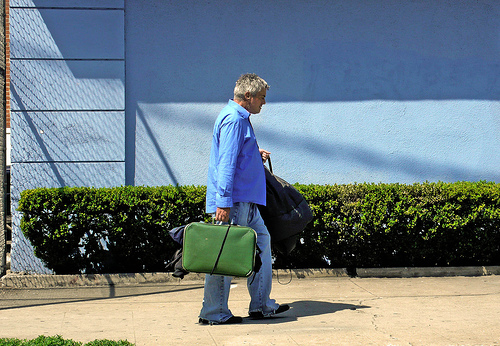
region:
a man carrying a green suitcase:
[175, 47, 314, 323]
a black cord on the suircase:
[217, 222, 229, 268]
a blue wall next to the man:
[274, 21, 474, 148]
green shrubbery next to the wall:
[334, 184, 484, 243]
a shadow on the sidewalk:
[295, 289, 371, 326]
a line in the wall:
[14, 99, 127, 119]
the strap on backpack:
[266, 154, 277, 168]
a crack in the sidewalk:
[356, 306, 396, 344]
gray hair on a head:
[240, 69, 263, 87]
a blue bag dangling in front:
[271, 186, 310, 231]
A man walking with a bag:
[167, 52, 304, 342]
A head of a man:
[216, 60, 280, 128]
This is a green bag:
[172, 212, 269, 286]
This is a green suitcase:
[173, 211, 266, 286]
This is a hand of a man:
[211, 112, 241, 226]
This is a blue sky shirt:
[201, 95, 270, 215]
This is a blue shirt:
[203, 96, 270, 216]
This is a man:
[174, 61, 301, 329]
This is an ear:
[241, 86, 255, 101]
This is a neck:
[228, 90, 254, 114]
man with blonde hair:
[224, 74, 281, 121]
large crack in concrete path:
[358, 297, 413, 344]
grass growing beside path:
[0, 326, 142, 343]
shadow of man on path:
[235, 285, 372, 335]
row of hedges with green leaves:
[321, 178, 498, 263]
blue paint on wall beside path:
[316, 98, 481, 176]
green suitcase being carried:
[168, 211, 265, 283]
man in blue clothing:
[155, 65, 340, 327]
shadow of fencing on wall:
[10, 4, 122, 174]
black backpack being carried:
[260, 168, 320, 239]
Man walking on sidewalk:
[186, 75, 301, 324]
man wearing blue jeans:
[180, 72, 315, 322]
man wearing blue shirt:
[198, 75, 315, 327]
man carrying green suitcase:
[176, 214, 256, 277]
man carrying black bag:
[257, 152, 312, 249]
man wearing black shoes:
[188, 73, 313, 328]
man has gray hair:
[192, 75, 318, 318]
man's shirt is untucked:
[198, 100, 273, 217]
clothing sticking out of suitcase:
[165, 217, 266, 284]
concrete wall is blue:
[12, 5, 497, 270]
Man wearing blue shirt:
[208, 63, 273, 206]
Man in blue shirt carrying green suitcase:
[181, 52, 266, 284]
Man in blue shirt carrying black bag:
[221, 71, 321, 229]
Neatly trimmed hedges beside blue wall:
[322, 173, 496, 259]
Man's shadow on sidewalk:
[279, 294, 371, 320]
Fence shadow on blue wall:
[9, 3, 113, 185]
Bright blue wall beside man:
[145, 30, 349, 187]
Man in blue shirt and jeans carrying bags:
[183, 62, 332, 327]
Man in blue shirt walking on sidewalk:
[170, 54, 327, 341]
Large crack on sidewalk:
[326, 297, 422, 342]